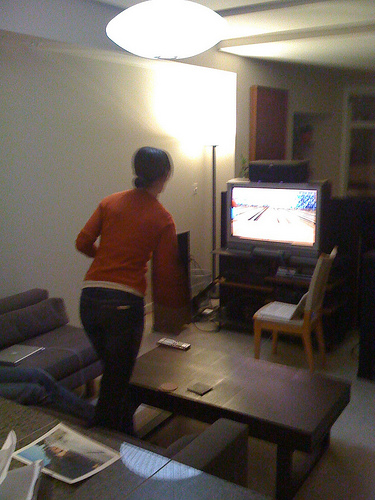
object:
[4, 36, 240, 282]
wall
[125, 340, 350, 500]
table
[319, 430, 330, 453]
stand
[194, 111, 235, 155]
shade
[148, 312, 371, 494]
floor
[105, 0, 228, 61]
light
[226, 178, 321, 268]
television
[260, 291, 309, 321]
laptop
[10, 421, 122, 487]
photo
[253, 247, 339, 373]
seat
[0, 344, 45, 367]
laptop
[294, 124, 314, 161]
someone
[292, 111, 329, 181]
door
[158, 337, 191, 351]
remote control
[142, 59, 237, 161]
light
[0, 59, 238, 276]
board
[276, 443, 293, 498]
legs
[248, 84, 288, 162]
chart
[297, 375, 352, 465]
edge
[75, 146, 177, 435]
woman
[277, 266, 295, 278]
wii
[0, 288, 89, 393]
sofa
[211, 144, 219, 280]
floor lamp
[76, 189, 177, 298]
shirt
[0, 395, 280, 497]
counter